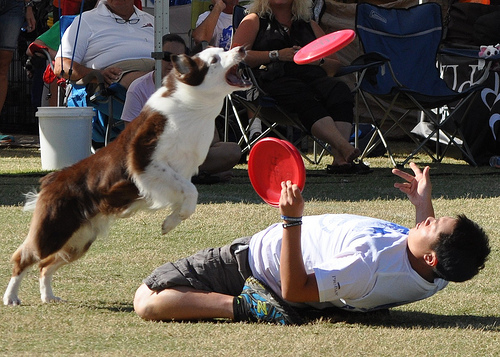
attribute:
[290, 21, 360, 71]
frisbee — red, round, plastic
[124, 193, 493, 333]
man — laying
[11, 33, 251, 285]
dog — white, brown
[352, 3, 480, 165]
chair — blue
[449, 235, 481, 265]
hair — dark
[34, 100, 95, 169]
bucket — white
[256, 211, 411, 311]
shirt — white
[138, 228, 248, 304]
shorts — gray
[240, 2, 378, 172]
woman — sitting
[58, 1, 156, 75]
man — sitting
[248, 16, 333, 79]
shirt — sleeveless, black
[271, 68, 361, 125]
pants — black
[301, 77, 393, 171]
legs — crossed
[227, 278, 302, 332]
shoe — blue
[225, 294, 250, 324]
sock — black